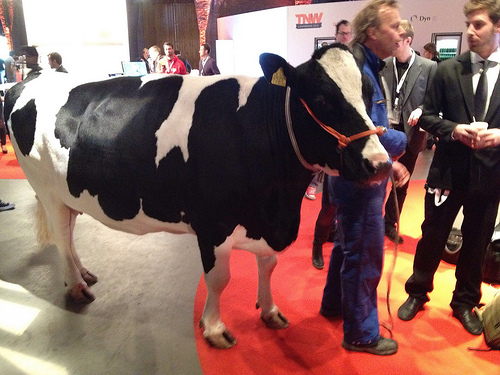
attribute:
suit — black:
[414, 51, 484, 305]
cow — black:
[6, 44, 409, 317]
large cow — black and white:
[28, 33, 441, 368]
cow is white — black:
[4, 27, 387, 372]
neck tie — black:
[464, 53, 498, 133]